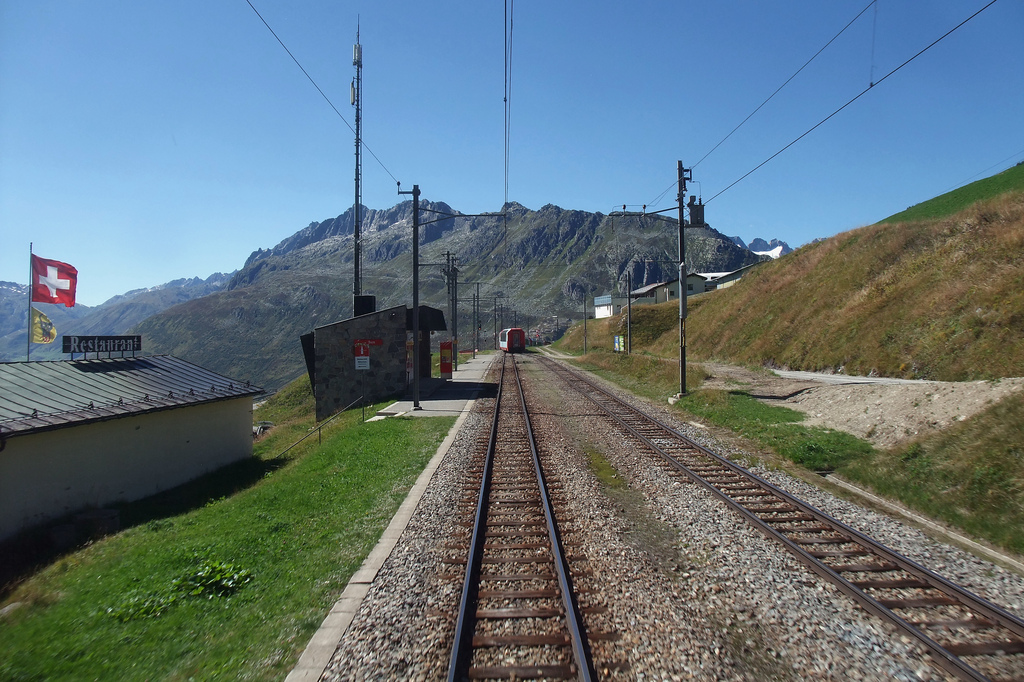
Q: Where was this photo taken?
A: On railroad tracks.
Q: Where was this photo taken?
A: The train tracks.